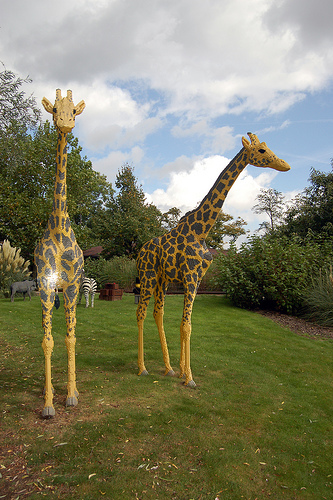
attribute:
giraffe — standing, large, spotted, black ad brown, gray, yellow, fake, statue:
[128, 129, 296, 393]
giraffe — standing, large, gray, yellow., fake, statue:
[31, 86, 91, 423]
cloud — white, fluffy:
[179, 98, 208, 126]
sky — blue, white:
[0, 2, 332, 252]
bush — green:
[225, 277, 270, 314]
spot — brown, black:
[183, 243, 197, 259]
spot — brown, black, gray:
[165, 244, 179, 257]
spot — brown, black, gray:
[60, 233, 76, 249]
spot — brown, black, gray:
[55, 168, 68, 183]